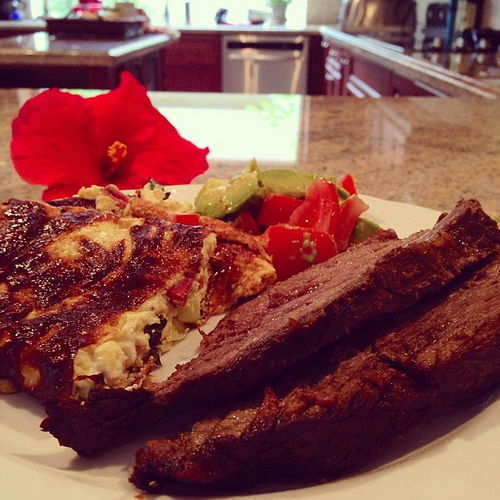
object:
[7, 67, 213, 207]
flower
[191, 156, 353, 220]
avocado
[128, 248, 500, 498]
meat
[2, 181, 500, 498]
plate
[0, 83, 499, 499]
table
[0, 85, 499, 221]
granite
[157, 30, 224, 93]
cabinet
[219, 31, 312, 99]
dish washer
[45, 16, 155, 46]
basket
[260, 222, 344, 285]
casserole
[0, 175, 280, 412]
frittata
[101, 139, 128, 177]
stem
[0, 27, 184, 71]
island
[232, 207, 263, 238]
tomato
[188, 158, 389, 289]
salad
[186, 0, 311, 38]
window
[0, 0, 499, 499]
kitchen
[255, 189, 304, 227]
pepper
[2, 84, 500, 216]
counter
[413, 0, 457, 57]
stove